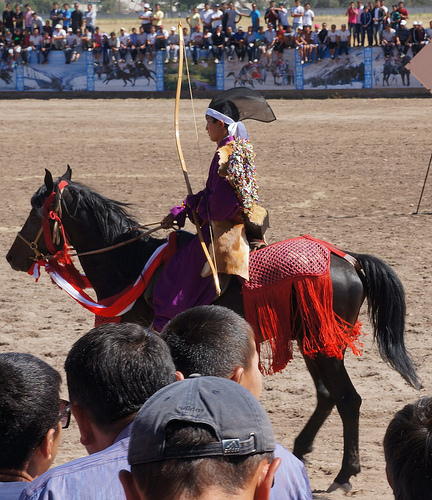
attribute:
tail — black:
[356, 251, 425, 391]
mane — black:
[71, 187, 136, 242]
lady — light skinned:
[176, 96, 263, 266]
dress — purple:
[149, 142, 276, 322]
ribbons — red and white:
[30, 233, 176, 323]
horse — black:
[5, 160, 422, 498]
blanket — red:
[241, 236, 363, 376]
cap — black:
[126, 371, 277, 466]